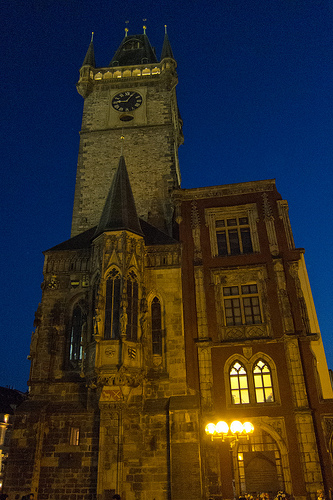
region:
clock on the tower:
[107, 84, 143, 111]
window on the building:
[229, 359, 248, 402]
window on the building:
[253, 355, 275, 405]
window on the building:
[224, 300, 238, 329]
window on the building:
[246, 297, 261, 325]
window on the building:
[217, 236, 226, 259]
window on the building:
[230, 230, 239, 253]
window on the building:
[244, 230, 251, 254]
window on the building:
[223, 286, 238, 295]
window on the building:
[240, 287, 258, 295]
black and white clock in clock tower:
[113, 87, 143, 116]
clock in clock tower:
[106, 89, 155, 118]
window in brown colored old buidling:
[98, 264, 121, 352]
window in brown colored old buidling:
[121, 274, 139, 338]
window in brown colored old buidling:
[145, 287, 176, 371]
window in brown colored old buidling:
[65, 291, 89, 376]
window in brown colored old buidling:
[219, 350, 253, 417]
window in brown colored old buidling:
[246, 349, 280, 407]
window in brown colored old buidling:
[222, 274, 267, 332]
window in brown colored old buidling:
[203, 204, 264, 271]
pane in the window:
[235, 390, 248, 409]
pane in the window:
[228, 388, 239, 403]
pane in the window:
[254, 388, 261, 402]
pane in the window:
[263, 387, 274, 399]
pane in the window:
[256, 376, 264, 385]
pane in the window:
[260, 374, 268, 386]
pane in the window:
[255, 316, 260, 322]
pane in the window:
[224, 318, 235, 327]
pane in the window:
[247, 285, 259, 293]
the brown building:
[47, 165, 329, 493]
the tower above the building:
[48, 15, 185, 231]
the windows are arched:
[221, 344, 280, 400]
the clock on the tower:
[102, 85, 152, 115]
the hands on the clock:
[113, 89, 131, 101]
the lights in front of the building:
[191, 412, 260, 446]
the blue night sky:
[228, 50, 260, 108]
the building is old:
[37, 23, 306, 494]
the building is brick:
[63, 45, 298, 492]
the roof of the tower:
[78, 34, 194, 69]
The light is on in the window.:
[227, 359, 284, 417]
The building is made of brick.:
[80, 409, 163, 498]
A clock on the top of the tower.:
[95, 84, 160, 129]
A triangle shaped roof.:
[92, 155, 151, 248]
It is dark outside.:
[209, 31, 296, 151]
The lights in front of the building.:
[191, 414, 261, 443]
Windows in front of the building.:
[101, 267, 142, 345]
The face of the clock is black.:
[110, 84, 150, 119]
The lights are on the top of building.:
[90, 69, 160, 92]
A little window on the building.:
[55, 423, 93, 460]